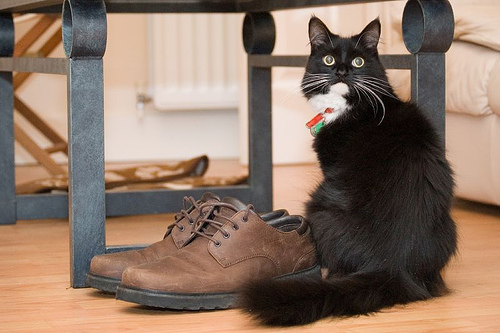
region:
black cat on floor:
[257, 16, 463, 322]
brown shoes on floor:
[87, 191, 313, 310]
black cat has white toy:
[302, 87, 348, 134]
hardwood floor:
[7, 194, 494, 329]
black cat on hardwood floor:
[230, 19, 457, 326]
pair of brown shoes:
[91, 192, 316, 310]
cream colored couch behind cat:
[379, 3, 497, 216]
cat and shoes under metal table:
[8, 14, 494, 311]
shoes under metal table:
[6, 6, 315, 316]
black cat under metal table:
[254, 4, 462, 330]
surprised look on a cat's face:
[302, 15, 389, 115]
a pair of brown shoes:
[87, 193, 319, 312]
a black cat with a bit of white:
[236, 14, 458, 325]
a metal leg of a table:
[60, 4, 109, 288]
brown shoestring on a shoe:
[190, 198, 252, 244]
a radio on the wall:
[136, 16, 247, 113]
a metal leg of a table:
[401, 1, 455, 151]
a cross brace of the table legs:
[0, 54, 68, 76]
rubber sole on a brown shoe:
[114, 267, 325, 311]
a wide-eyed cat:
[316, 50, 371, 70]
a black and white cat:
[240, 15, 460, 323]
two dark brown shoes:
[84, 189, 314, 306]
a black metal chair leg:
[60, 2, 107, 285]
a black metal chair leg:
[0, 2, 17, 224]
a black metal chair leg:
[243, 10, 274, 210]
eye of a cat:
[353, 55, 364, 67]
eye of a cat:
[321, 52, 334, 65]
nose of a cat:
[335, 60, 348, 73]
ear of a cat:
[307, 13, 334, 51]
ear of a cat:
[358, 16, 380, 49]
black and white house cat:
[228, 16, 461, 323]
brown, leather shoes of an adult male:
[50, 159, 340, 327]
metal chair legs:
[0, 9, 470, 324]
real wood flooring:
[0, 144, 489, 327]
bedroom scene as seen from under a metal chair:
[8, 15, 467, 321]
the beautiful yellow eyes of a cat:
[291, 12, 406, 107]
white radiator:
[130, 1, 279, 140]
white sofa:
[354, 1, 493, 233]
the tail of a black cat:
[225, 241, 451, 326]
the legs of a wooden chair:
[0, 20, 123, 212]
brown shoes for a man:
[66, 184, 332, 316]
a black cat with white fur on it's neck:
[232, 17, 462, 326]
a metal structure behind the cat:
[1, 3, 461, 296]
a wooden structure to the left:
[0, 1, 69, 182]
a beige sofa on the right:
[375, 0, 497, 224]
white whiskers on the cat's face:
[272, 72, 402, 125]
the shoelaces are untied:
[162, 188, 255, 258]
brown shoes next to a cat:
[71, 15, 466, 330]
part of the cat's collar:
[261, 100, 358, 140]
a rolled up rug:
[17, 158, 277, 206]